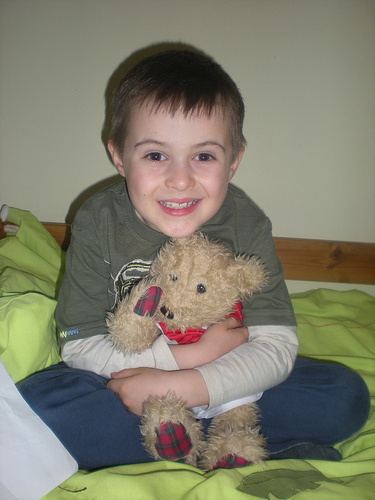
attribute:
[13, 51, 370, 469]
boy — young, smiling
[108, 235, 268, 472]
teddy bear — stuffed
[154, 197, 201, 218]
smile — wide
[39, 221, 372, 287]
frame — wooden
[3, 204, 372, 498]
sheets — lime green, green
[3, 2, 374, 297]
wall — ivory